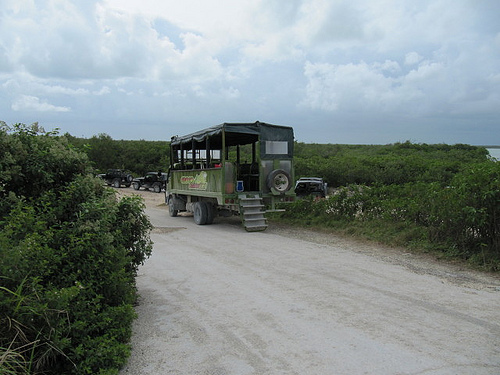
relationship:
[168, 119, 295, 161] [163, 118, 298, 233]
top of bus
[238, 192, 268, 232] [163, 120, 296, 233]
stairs on bus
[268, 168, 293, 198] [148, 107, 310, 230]
tire on back of truck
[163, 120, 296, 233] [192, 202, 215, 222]
bus has tire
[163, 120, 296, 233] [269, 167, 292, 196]
bus has tire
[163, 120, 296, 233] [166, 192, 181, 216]
bus has tire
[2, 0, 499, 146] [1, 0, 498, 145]
clouds in sky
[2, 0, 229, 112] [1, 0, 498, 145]
clouds in sky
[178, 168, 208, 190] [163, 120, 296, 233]
logo on bus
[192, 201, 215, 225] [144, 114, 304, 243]
tire on back of truck